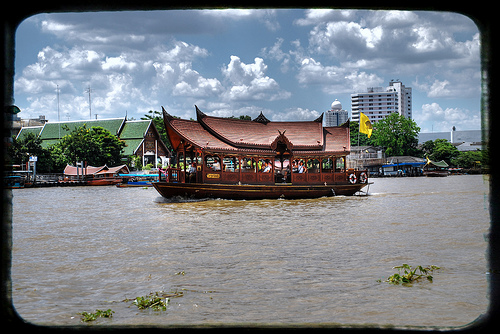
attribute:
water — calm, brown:
[12, 175, 490, 328]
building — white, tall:
[349, 78, 413, 135]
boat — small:
[117, 178, 151, 188]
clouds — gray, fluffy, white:
[15, 2, 485, 129]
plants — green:
[70, 258, 442, 326]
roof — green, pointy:
[14, 117, 172, 160]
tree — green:
[54, 121, 127, 171]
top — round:
[331, 97, 342, 111]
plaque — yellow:
[205, 172, 221, 180]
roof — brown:
[159, 102, 353, 156]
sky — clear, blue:
[11, 9, 487, 131]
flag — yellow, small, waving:
[352, 111, 382, 142]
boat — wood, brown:
[151, 104, 375, 199]